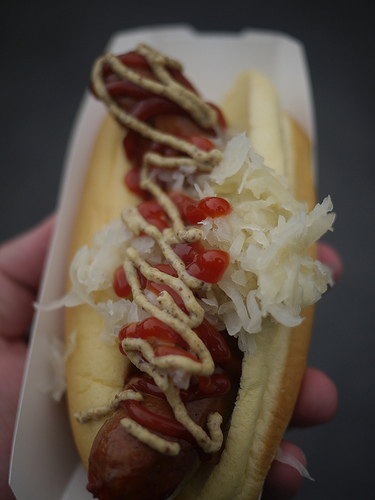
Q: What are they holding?
A: A hot dog.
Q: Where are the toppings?
A: On top of the hot dog.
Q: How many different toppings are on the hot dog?
A: 3.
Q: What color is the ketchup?
A: Red.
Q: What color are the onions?
A: White.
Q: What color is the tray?
A: White.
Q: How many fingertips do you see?
A: 3.